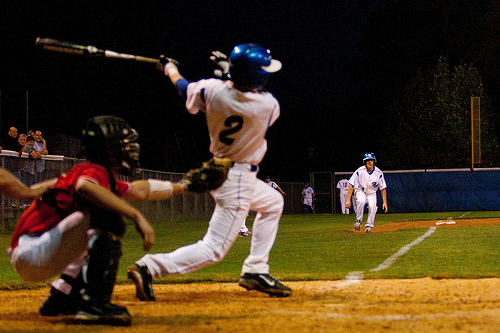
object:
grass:
[463, 208, 497, 264]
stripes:
[362, 222, 411, 258]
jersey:
[6, 160, 129, 256]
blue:
[254, 84, 263, 88]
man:
[345, 152, 389, 234]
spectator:
[0, 126, 48, 160]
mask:
[110, 129, 141, 177]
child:
[6, 115, 235, 322]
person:
[22, 136, 42, 160]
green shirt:
[25, 144, 38, 154]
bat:
[35, 36, 159, 64]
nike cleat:
[238, 272, 292, 298]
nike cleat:
[127, 264, 156, 301]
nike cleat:
[72, 294, 131, 322]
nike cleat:
[38, 285, 86, 321]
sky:
[8, 6, 175, 28]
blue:
[219, 115, 244, 145]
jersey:
[186, 78, 281, 166]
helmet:
[228, 43, 282, 88]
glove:
[157, 54, 179, 70]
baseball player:
[127, 44, 292, 302]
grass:
[377, 232, 407, 247]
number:
[219, 114, 245, 145]